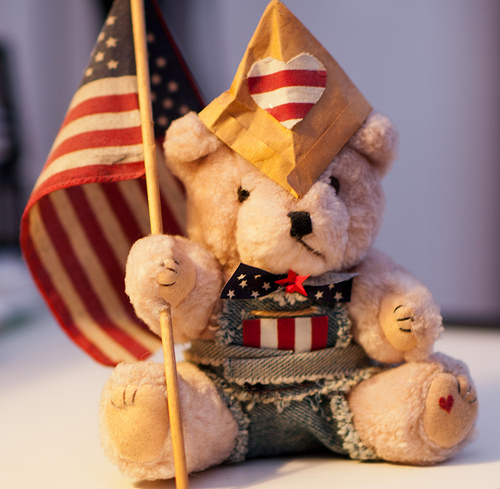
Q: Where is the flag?
A: Bear's hand.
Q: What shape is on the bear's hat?
A: Heart.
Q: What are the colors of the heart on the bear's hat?
A: Red and white.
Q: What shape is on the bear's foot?
A: Heart.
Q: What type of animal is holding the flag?
A: Bear.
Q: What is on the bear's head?
A: Paper hat.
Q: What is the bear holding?
A: American flag.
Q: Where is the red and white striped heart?
A: On the bear's hat.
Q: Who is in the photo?
A: A teddy bear.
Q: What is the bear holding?
A: An American flag.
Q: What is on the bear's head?
A: A paper hat.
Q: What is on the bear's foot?
A: A little heart.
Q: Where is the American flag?
A: In the bear's paw.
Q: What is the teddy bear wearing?
A: A patriotic denim jumper.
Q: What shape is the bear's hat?
A: Triangle.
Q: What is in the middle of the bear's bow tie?
A: A red star.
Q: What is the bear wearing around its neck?
A: A bow tie.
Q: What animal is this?
A: Teddy bear.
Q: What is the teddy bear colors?
A: American colors.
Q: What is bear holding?
A: American flag.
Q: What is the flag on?
A: Wooden dowel.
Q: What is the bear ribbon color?
A: Blue.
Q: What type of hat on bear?
A: Paper.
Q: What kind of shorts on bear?
A: Denim.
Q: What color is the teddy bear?
A: White.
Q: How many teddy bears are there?
A: One.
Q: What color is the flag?
A: Red, white, and blue.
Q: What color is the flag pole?
A: Brown.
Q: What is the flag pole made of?
A: Wood.